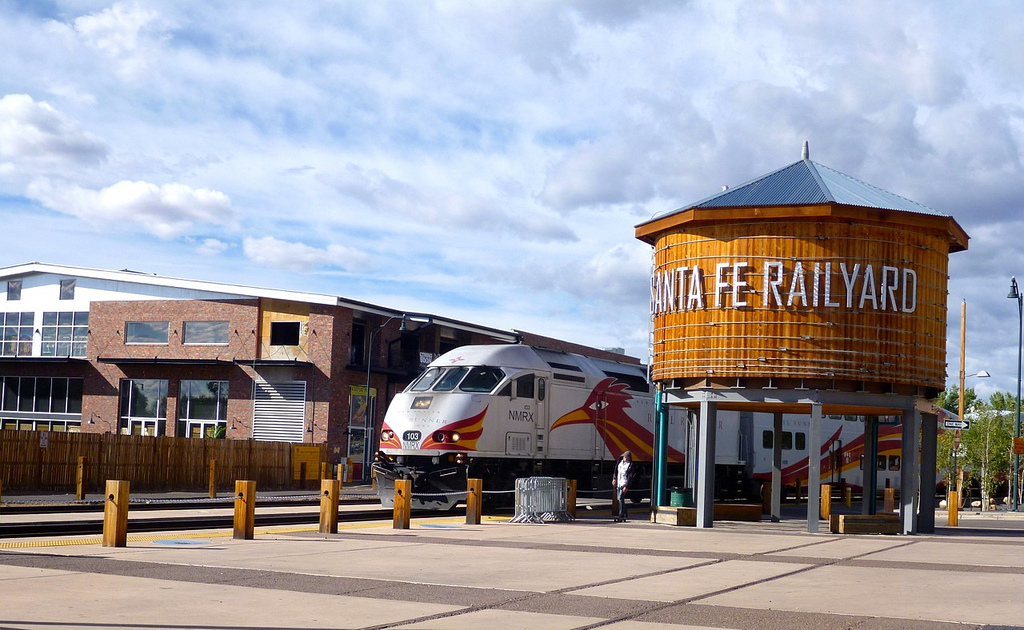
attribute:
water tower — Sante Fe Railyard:
[629, 132, 973, 534]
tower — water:
[653, 182, 934, 433]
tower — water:
[582, 176, 935, 522]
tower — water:
[614, 150, 964, 514]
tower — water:
[629, 189, 902, 451]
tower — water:
[655, 180, 954, 533]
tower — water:
[605, 186, 981, 584]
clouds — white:
[361, 121, 489, 228]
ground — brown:
[450, 547, 585, 608]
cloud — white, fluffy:
[446, 169, 540, 288]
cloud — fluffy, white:
[411, 225, 522, 271]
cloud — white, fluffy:
[795, 50, 899, 139]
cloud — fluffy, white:
[679, 40, 777, 123]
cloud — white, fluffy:
[409, 81, 503, 192]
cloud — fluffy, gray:
[541, 136, 710, 204]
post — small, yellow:
[105, 476, 132, 548]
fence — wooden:
[10, 432, 361, 487]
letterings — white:
[653, 255, 934, 320]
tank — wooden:
[641, 154, 970, 377]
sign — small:
[934, 411, 987, 433]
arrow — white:
[932, 409, 972, 442]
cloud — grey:
[833, 42, 1022, 220]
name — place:
[660, 264, 928, 321]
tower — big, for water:
[641, 152, 964, 531]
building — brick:
[88, 288, 400, 476]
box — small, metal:
[518, 472, 585, 522]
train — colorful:
[379, 337, 889, 500]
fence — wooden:
[1, 433, 323, 494]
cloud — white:
[12, 87, 250, 252]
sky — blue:
[5, 3, 1021, 366]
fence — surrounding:
[12, 413, 328, 480]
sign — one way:
[899, 398, 990, 440]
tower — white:
[608, 175, 1021, 457]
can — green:
[616, 432, 742, 553]